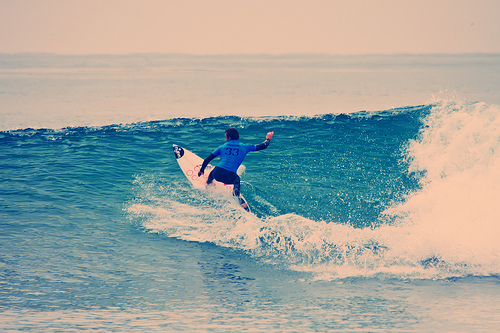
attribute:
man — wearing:
[196, 125, 275, 200]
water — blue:
[11, 107, 498, 330]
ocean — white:
[7, 133, 141, 279]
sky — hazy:
[23, 7, 497, 77]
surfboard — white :
[172, 137, 251, 208]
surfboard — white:
[175, 135, 232, 202]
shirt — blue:
[202, 133, 275, 190]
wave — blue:
[358, 73, 492, 280]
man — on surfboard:
[199, 125, 252, 230]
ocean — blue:
[1, 52, 497, 330]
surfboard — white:
[158, 130, 258, 208]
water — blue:
[252, 62, 346, 104]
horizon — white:
[3, 33, 495, 80]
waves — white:
[156, 132, 497, 274]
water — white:
[305, 120, 361, 187]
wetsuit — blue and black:
[201, 129, 266, 200]